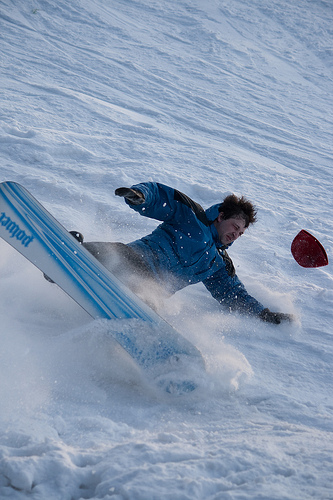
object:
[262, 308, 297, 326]
glove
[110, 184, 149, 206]
hand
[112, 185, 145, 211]
glove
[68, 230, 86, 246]
shoe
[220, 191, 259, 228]
hair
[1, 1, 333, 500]
snow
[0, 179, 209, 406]
snowboard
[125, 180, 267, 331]
parka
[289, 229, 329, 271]
hat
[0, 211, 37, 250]
logo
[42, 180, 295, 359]
man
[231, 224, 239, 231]
eye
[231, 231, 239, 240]
nose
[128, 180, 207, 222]
arm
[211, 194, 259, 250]
head